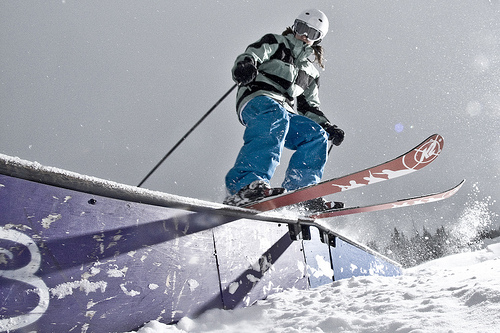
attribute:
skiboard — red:
[275, 137, 468, 232]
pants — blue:
[227, 92, 328, 182]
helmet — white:
[294, 6, 334, 34]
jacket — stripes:
[250, 38, 329, 120]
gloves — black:
[227, 61, 346, 146]